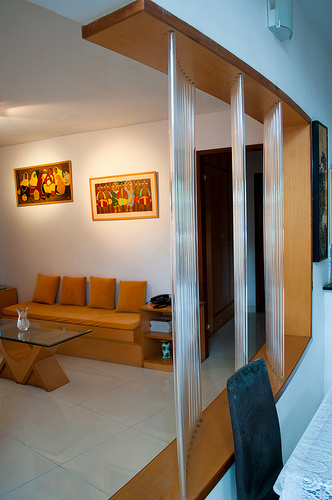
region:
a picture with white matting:
[88, 168, 163, 224]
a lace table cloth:
[272, 384, 330, 498]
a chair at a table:
[220, 356, 289, 496]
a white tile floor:
[7, 381, 165, 487]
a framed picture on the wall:
[11, 155, 73, 209]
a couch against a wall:
[7, 269, 147, 367]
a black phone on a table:
[151, 288, 169, 311]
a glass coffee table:
[1, 318, 101, 380]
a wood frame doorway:
[189, 145, 264, 330]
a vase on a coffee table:
[14, 304, 34, 334]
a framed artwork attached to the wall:
[89, 171, 159, 220]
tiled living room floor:
[0, 360, 172, 497]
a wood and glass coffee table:
[0, 316, 92, 392]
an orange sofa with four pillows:
[4, 272, 142, 327]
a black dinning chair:
[224, 357, 282, 498]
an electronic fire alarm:
[267, 1, 294, 41]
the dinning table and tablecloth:
[281, 383, 330, 498]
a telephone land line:
[149, 292, 170, 309]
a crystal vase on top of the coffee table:
[15, 306, 30, 331]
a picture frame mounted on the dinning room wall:
[312, 119, 328, 262]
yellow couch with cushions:
[19, 269, 156, 330]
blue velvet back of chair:
[231, 350, 267, 499]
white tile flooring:
[24, 393, 151, 490]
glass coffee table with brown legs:
[1, 327, 76, 384]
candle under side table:
[152, 336, 174, 368]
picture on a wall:
[85, 161, 158, 231]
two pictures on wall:
[0, 138, 142, 241]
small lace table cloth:
[275, 411, 327, 499]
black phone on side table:
[137, 287, 167, 314]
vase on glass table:
[18, 300, 37, 344]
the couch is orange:
[6, 263, 182, 378]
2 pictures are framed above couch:
[7, 155, 201, 249]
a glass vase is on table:
[8, 297, 58, 351]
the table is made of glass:
[1, 308, 90, 404]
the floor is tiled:
[1, 368, 165, 485]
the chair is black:
[221, 360, 296, 492]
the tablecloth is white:
[281, 415, 327, 498]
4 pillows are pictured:
[36, 264, 146, 310]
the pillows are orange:
[23, 263, 171, 309]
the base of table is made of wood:
[0, 338, 76, 394]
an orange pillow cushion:
[30, 270, 59, 306]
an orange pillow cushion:
[57, 273, 87, 309]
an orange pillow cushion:
[85, 275, 114, 312]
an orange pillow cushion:
[114, 275, 147, 312]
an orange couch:
[5, 273, 153, 362]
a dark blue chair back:
[223, 351, 288, 498]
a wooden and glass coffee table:
[0, 315, 95, 389]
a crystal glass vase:
[14, 305, 30, 332]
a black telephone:
[146, 288, 173, 311]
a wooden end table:
[138, 291, 209, 372]